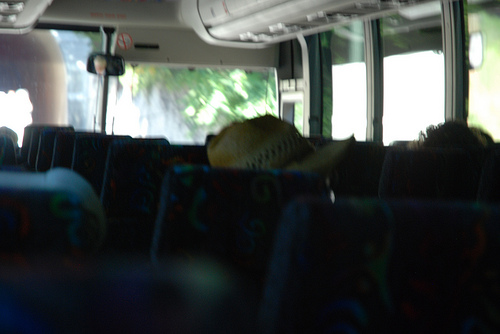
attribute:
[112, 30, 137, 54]
sticker — red, warning, inside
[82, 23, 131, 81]
mirror — mounted, rear view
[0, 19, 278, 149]
window — large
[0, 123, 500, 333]
seats — colored, blue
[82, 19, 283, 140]
leaves — green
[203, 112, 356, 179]
hat — straw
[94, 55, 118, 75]
reflection — driver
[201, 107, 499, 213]
people — sitting, inside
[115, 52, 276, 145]
tree — green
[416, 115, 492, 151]
hair — black